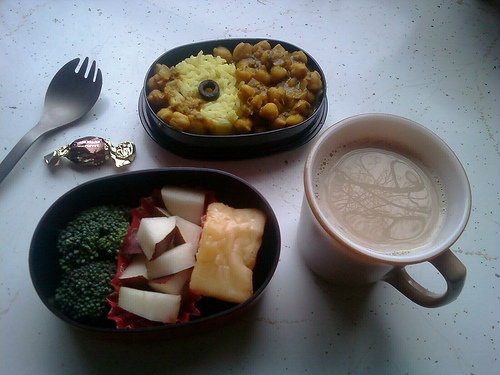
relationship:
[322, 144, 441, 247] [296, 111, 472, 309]
coffee in coffee mug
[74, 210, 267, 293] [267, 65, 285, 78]
food in beans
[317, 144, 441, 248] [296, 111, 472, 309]
coffee in coffee mug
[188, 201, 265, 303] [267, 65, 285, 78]
cheese on beans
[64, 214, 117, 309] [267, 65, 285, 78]
broccoli inside beans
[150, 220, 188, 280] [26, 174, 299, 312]
apple inside bowl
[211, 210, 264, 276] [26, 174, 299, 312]
cheese in bowl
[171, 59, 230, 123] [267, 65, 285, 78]
rice in beans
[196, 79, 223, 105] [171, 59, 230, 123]
olive on top of rice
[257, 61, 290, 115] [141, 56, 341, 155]
beans in bowl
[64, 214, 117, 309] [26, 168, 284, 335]
broccoli in bowl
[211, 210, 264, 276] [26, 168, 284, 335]
cheese in bowl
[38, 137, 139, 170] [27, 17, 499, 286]
candy on table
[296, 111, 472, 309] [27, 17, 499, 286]
coffee mug on top of table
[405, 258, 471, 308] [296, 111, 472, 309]
handle on coffee mug